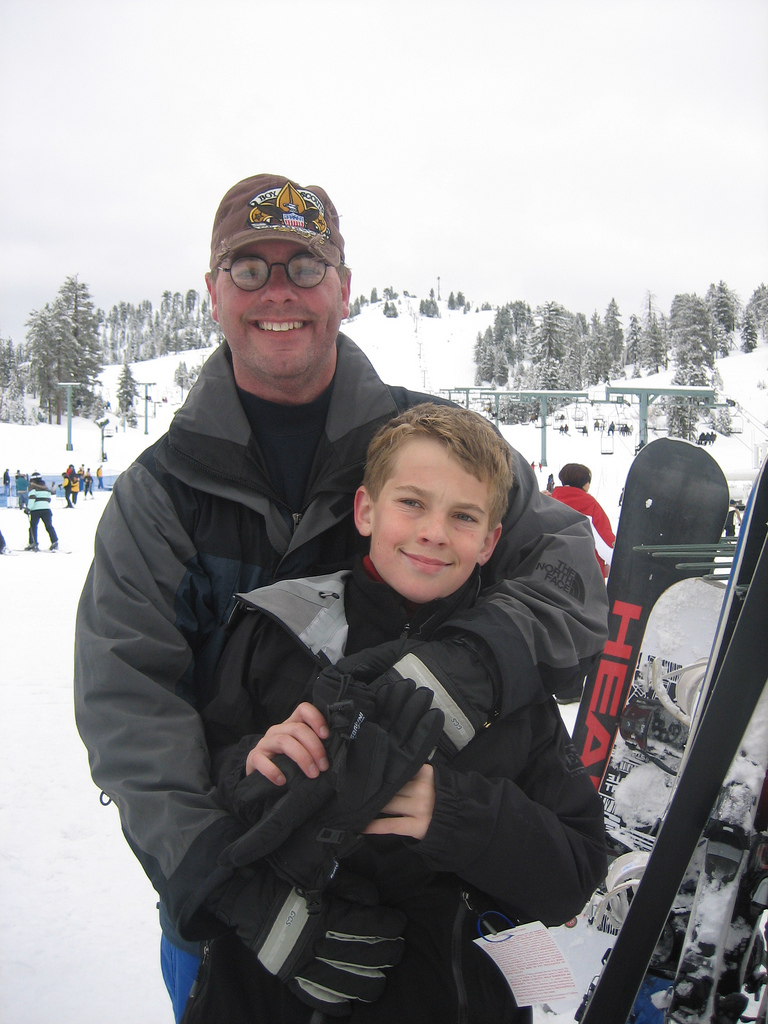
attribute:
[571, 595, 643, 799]
writing — red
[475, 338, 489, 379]
snow — white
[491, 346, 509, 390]
snow — white 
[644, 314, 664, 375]
snow — white 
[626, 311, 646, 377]
snow — white 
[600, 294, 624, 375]
snow — white 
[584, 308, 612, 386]
snow — white 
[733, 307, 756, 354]
snow — white 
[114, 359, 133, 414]
snow — white 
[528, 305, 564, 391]
snow — white 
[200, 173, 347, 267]
cap — brown 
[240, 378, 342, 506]
shirt — black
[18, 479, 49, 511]
coat — blue, brown